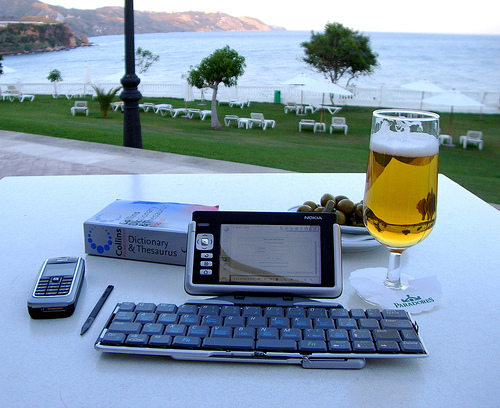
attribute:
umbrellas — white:
[288, 75, 353, 100]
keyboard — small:
[97, 301, 429, 358]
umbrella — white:
[294, 77, 354, 105]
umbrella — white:
[283, 71, 318, 104]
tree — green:
[297, 18, 381, 105]